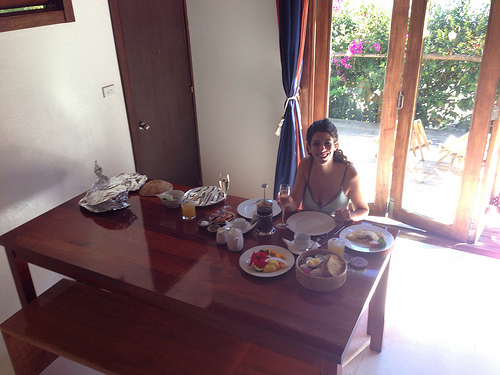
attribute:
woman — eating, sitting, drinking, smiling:
[282, 119, 369, 221]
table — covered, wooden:
[1, 175, 401, 374]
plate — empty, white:
[285, 211, 334, 237]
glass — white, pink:
[279, 184, 289, 227]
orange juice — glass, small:
[182, 199, 196, 218]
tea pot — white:
[227, 225, 243, 253]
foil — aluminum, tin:
[80, 160, 147, 213]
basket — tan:
[295, 249, 348, 291]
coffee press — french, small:
[255, 184, 276, 236]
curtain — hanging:
[274, 1, 307, 205]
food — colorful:
[249, 247, 289, 272]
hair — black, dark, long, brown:
[305, 118, 351, 167]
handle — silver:
[138, 120, 149, 131]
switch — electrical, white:
[103, 82, 114, 97]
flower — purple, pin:
[349, 40, 363, 52]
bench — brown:
[1, 277, 329, 374]